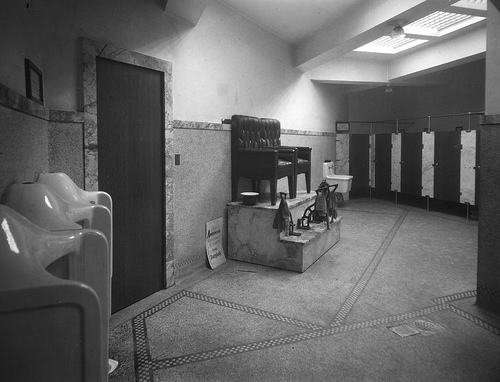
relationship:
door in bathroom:
[88, 41, 199, 312] [4, 5, 494, 374]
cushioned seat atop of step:
[260, 118, 314, 190] [282, 210, 342, 273]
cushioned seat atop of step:
[230, 114, 296, 205] [282, 210, 342, 273]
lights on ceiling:
[329, 3, 497, 76] [279, 9, 494, 69]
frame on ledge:
[24, 53, 51, 102] [4, 78, 81, 128]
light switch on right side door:
[174, 152, 182, 169] [94, 56, 166, 314]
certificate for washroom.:
[16, 61, 61, 124] [135, 62, 499, 362]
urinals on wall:
[0, 205, 113, 382] [14, 133, 74, 182]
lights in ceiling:
[351, 34, 429, 56] [247, 26, 459, 52]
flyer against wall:
[205, 216, 228, 270] [52, 2, 348, 309]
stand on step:
[227, 183, 342, 278] [241, 182, 323, 223]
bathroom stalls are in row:
[332, 112, 482, 208] [315, 102, 490, 212]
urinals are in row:
[6, 151, 297, 370] [0, 174, 114, 378]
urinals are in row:
[2, 163, 136, 381] [0, 174, 114, 378]